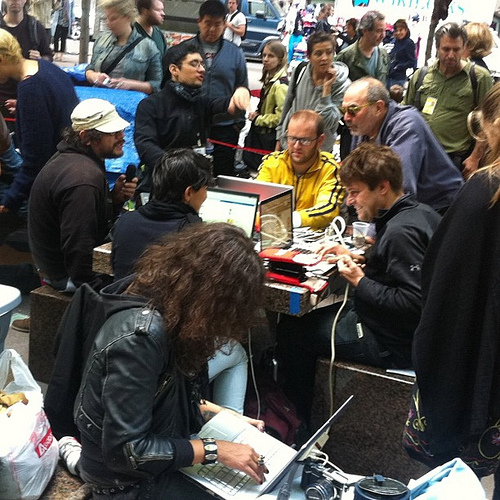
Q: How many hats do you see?
A: One.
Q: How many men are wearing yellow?
A: One.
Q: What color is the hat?
A: Light brown.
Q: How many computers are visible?
A: One.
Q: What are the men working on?
A: Computers.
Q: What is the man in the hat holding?
A: A microphone.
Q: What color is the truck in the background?
A: Blue.